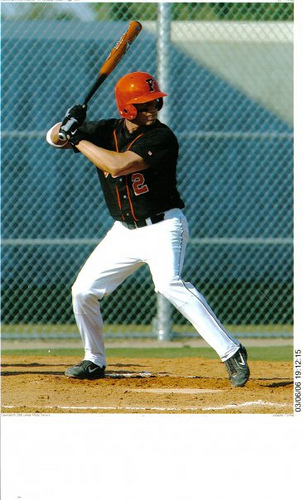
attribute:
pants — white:
[81, 237, 261, 385]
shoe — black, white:
[225, 341, 247, 386]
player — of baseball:
[46, 20, 253, 387]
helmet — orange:
[116, 67, 165, 117]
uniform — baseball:
[69, 120, 185, 218]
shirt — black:
[88, 117, 205, 224]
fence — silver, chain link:
[1, 0, 294, 338]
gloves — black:
[52, 97, 92, 154]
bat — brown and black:
[56, 19, 146, 139]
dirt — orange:
[106, 355, 222, 411]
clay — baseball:
[11, 378, 292, 419]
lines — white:
[31, 400, 288, 417]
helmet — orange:
[91, 66, 195, 118]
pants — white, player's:
[71, 207, 240, 368]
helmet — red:
[109, 72, 165, 120]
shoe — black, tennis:
[218, 342, 251, 387]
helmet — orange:
[90, 68, 173, 110]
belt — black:
[109, 212, 168, 228]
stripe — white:
[6, 398, 293, 410]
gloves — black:
[56, 98, 88, 147]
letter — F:
[143, 76, 158, 91]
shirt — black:
[74, 113, 190, 224]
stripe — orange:
[106, 127, 139, 211]